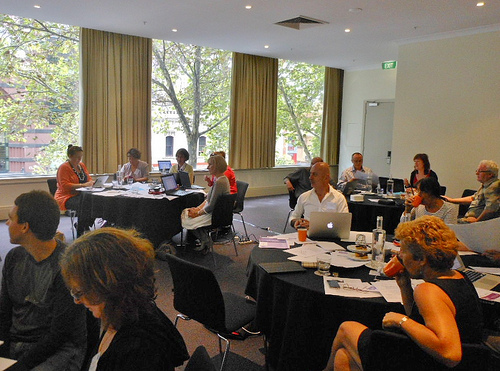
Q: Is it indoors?
A: Yes, it is indoors.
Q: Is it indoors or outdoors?
A: It is indoors.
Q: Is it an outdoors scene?
A: No, it is indoors.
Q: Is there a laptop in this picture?
A: Yes, there is a laptop.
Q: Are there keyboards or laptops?
A: Yes, there is a laptop.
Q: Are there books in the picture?
A: No, there are no books.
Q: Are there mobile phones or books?
A: No, there are no books or mobile phones.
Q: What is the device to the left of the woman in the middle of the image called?
A: The device is a laptop.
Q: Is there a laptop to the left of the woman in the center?
A: Yes, there is a laptop to the left of the woman.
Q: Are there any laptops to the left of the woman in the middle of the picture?
A: Yes, there is a laptop to the left of the woman.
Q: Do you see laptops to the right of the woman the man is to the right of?
A: No, the laptop is to the left of the woman.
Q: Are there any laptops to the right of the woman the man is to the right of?
A: No, the laptop is to the left of the woman.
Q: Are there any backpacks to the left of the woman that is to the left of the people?
A: No, there is a laptop to the left of the woman.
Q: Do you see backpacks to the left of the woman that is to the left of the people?
A: No, there is a laptop to the left of the woman.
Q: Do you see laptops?
A: Yes, there is a laptop.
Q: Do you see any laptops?
A: Yes, there is a laptop.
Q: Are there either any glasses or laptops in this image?
A: Yes, there is a laptop.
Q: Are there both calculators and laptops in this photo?
A: No, there is a laptop but no calculators.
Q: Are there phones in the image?
A: No, there are no phones.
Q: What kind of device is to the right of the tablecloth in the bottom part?
A: The device is a laptop.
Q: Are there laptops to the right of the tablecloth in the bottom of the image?
A: Yes, there is a laptop to the right of the tablecloth.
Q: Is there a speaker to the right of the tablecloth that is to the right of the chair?
A: No, there is a laptop to the right of the tablecloth.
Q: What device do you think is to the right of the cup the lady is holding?
A: The device is a laptop.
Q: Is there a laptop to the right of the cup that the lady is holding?
A: Yes, there is a laptop to the right of the cup.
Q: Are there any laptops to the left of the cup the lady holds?
A: No, the laptop is to the right of the cup.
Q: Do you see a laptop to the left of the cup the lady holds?
A: No, the laptop is to the right of the cup.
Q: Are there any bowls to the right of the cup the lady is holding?
A: No, there is a laptop to the right of the cup.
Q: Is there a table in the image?
A: Yes, there is a table.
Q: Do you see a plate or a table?
A: Yes, there is a table.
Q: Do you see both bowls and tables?
A: No, there is a table but no bowls.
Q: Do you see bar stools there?
A: No, there are no bar stools.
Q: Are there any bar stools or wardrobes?
A: No, there are no bar stools or wardrobes.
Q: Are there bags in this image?
A: No, there are no bags.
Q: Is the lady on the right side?
A: Yes, the lady is on the right of the image.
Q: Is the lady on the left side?
A: No, the lady is on the right of the image.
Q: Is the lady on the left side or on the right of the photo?
A: The lady is on the right of the image.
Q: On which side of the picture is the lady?
A: The lady is on the right of the image.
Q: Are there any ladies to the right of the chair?
A: Yes, there is a lady to the right of the chair.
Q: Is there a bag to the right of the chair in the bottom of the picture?
A: No, there is a lady to the right of the chair.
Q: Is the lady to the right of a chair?
A: Yes, the lady is to the right of a chair.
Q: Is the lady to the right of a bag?
A: No, the lady is to the right of a chair.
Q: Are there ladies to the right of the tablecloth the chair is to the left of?
A: Yes, there is a lady to the right of the tablecloth.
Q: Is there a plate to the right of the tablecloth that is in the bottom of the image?
A: No, there is a lady to the right of the tablecloth.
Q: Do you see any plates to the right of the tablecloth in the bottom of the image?
A: No, there is a lady to the right of the tablecloth.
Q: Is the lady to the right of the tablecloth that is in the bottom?
A: Yes, the lady is to the right of the tablecloth.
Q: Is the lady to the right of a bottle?
A: No, the lady is to the right of the tablecloth.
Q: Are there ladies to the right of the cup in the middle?
A: Yes, there is a lady to the right of the cup.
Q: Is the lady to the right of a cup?
A: Yes, the lady is to the right of a cup.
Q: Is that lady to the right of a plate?
A: No, the lady is to the right of a cup.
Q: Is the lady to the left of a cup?
A: No, the lady is to the right of a cup.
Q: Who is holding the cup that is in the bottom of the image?
A: The lady is holding the cup.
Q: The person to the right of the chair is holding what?
A: The lady is holding the cup.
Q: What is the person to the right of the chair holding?
A: The lady is holding the cup.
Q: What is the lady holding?
A: The lady is holding the cup.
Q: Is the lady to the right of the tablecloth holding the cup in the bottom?
A: Yes, the lady is holding the cup.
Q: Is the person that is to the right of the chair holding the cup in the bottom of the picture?
A: Yes, the lady is holding the cup.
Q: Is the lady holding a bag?
A: No, the lady is holding the cup.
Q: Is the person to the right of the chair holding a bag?
A: No, the lady is holding the cup.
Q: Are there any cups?
A: Yes, there is a cup.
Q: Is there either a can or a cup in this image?
A: Yes, there is a cup.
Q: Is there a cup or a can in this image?
A: Yes, there is a cup.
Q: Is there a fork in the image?
A: No, there are no forks.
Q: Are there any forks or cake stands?
A: No, there are no forks or cake stands.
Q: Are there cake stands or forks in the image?
A: No, there are no forks or cake stands.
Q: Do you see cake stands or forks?
A: No, there are no forks or cake stands.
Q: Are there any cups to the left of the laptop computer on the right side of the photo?
A: Yes, there is a cup to the left of the laptop.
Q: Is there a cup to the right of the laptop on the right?
A: No, the cup is to the left of the laptop computer.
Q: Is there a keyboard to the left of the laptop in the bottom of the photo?
A: No, there is a cup to the left of the laptop.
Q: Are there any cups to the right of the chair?
A: Yes, there is a cup to the right of the chair.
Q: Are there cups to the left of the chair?
A: No, the cup is to the right of the chair.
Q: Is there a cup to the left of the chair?
A: No, the cup is to the right of the chair.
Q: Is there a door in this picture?
A: Yes, there is a door.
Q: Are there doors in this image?
A: Yes, there is a door.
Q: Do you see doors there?
A: Yes, there is a door.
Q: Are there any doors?
A: Yes, there is a door.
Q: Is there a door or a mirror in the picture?
A: Yes, there is a door.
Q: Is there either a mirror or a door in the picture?
A: Yes, there is a door.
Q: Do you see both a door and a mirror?
A: No, there is a door but no mirrors.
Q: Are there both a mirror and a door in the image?
A: No, there is a door but no mirrors.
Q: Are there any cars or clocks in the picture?
A: No, there are no cars or clocks.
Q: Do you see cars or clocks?
A: No, there are no cars or clocks.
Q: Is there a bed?
A: No, there are no beds.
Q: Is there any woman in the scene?
A: Yes, there is a woman.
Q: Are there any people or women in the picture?
A: Yes, there is a woman.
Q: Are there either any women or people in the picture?
A: Yes, there is a woman.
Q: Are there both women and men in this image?
A: Yes, there are both a woman and a man.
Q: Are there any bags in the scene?
A: No, there are no bags.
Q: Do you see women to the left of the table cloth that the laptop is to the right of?
A: Yes, there is a woman to the left of the tablecloth.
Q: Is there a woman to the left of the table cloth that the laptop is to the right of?
A: Yes, there is a woman to the left of the tablecloth.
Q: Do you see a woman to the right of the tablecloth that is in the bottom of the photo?
A: No, the woman is to the left of the tablecloth.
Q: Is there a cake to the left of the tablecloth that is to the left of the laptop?
A: No, there is a woman to the left of the tablecloth.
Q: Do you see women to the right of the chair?
A: No, the woman is to the left of the chair.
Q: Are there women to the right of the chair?
A: No, the woman is to the left of the chair.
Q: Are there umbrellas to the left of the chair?
A: No, there is a woman to the left of the chair.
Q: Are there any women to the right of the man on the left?
A: Yes, there is a woman to the right of the man.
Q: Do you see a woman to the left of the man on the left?
A: No, the woman is to the right of the man.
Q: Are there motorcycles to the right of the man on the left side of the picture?
A: No, there is a woman to the right of the man.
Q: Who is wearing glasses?
A: The woman is wearing glasses.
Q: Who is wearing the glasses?
A: The woman is wearing glasses.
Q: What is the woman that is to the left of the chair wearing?
A: The woman is wearing glasses.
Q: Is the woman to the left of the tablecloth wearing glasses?
A: Yes, the woman is wearing glasses.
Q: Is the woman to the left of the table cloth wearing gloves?
A: No, the woman is wearing glasses.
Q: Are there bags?
A: No, there are no bags.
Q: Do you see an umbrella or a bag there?
A: No, there are no bags or umbrellas.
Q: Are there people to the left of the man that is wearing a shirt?
A: Yes, there are people to the left of the man.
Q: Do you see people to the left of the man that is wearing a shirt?
A: Yes, there are people to the left of the man.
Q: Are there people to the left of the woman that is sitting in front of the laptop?
A: Yes, there are people to the left of the woman.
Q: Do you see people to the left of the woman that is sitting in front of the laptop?
A: Yes, there are people to the left of the woman.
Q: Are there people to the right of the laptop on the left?
A: Yes, there are people to the right of the laptop.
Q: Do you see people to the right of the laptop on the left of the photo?
A: Yes, there are people to the right of the laptop.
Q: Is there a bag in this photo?
A: No, there are no bags.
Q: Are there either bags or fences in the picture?
A: No, there are no bags or fences.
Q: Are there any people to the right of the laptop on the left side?
A: Yes, there are people to the right of the laptop.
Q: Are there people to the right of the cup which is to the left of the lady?
A: No, the people are to the left of the cup.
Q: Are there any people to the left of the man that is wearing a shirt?
A: Yes, there are people to the left of the man.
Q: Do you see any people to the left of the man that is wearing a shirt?
A: Yes, there are people to the left of the man.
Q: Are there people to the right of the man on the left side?
A: Yes, there are people to the right of the man.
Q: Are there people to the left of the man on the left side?
A: No, the people are to the right of the man.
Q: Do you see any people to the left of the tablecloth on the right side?
A: Yes, there are people to the left of the tablecloth.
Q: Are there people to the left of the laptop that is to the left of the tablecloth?
A: Yes, there are people to the left of the laptop.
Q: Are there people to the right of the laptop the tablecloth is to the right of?
A: No, the people are to the left of the laptop.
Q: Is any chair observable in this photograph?
A: Yes, there is a chair.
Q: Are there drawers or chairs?
A: Yes, there is a chair.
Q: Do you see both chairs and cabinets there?
A: No, there is a chair but no cabinets.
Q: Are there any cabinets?
A: No, there are no cabinets.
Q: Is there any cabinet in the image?
A: No, there are no cabinets.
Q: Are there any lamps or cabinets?
A: No, there are no cabinets or lamps.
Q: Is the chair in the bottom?
A: Yes, the chair is in the bottom of the image.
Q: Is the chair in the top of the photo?
A: No, the chair is in the bottom of the image.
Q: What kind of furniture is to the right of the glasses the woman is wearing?
A: The piece of furniture is a chair.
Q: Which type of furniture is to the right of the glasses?
A: The piece of furniture is a chair.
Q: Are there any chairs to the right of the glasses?
A: Yes, there is a chair to the right of the glasses.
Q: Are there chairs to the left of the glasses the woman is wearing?
A: No, the chair is to the right of the glasses.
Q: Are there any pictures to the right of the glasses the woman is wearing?
A: No, there is a chair to the right of the glasses.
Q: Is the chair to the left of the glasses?
A: No, the chair is to the right of the glasses.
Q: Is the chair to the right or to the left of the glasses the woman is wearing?
A: The chair is to the right of the glasses.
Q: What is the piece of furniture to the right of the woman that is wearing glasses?
A: The piece of furniture is a chair.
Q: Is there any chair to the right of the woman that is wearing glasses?
A: Yes, there is a chair to the right of the woman.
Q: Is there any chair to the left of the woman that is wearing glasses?
A: No, the chair is to the right of the woman.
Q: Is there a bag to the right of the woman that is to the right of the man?
A: No, there is a chair to the right of the woman.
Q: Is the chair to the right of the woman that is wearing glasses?
A: Yes, the chair is to the right of the woman.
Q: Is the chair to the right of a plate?
A: No, the chair is to the right of the woman.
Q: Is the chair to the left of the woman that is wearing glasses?
A: No, the chair is to the right of the woman.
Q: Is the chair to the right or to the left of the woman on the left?
A: The chair is to the right of the woman.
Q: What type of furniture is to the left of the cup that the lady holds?
A: The piece of furniture is a chair.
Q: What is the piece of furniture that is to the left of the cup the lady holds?
A: The piece of furniture is a chair.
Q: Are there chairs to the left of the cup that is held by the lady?
A: Yes, there is a chair to the left of the cup.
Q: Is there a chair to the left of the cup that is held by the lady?
A: Yes, there is a chair to the left of the cup.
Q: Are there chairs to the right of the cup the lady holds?
A: No, the chair is to the left of the cup.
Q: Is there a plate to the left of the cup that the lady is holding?
A: No, there is a chair to the left of the cup.